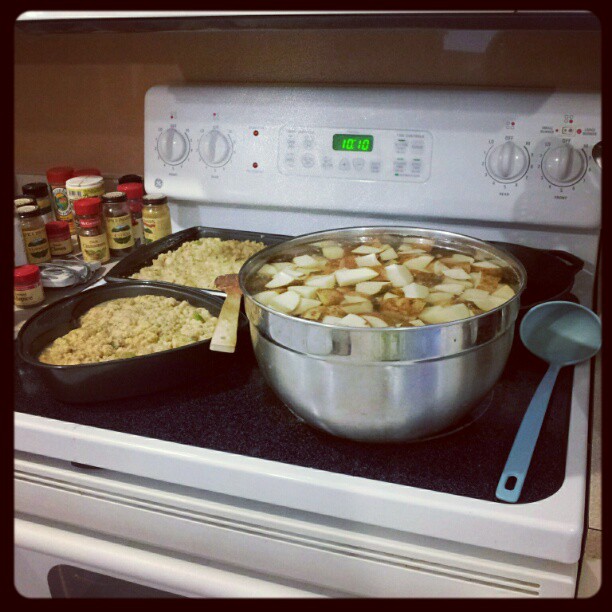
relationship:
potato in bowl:
[293, 246, 319, 266] [239, 226, 525, 444]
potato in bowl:
[442, 260, 469, 280] [239, 226, 525, 444]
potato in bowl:
[265, 269, 292, 286] [239, 226, 525, 444]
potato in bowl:
[404, 281, 427, 299] [239, 226, 525, 444]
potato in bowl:
[333, 264, 377, 287] [239, 226, 525, 444]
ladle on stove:
[492, 300, 601, 505] [9, 79, 583, 611]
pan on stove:
[20, 279, 235, 396] [9, 79, 583, 611]